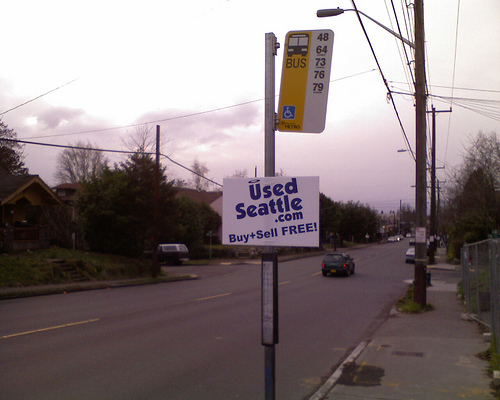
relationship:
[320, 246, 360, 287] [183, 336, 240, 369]
car on street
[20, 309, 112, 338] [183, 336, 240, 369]
line on street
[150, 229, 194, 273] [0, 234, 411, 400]
vehicle in street